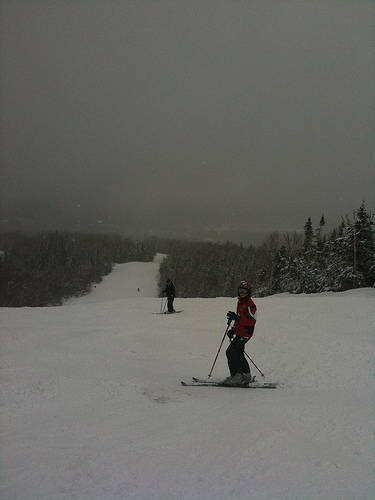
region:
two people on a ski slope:
[154, 278, 282, 388]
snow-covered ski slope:
[2, 253, 373, 498]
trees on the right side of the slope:
[158, 206, 372, 298]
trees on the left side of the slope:
[4, 232, 151, 304]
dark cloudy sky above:
[1, 4, 373, 239]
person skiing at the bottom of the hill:
[135, 286, 141, 291]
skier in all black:
[154, 280, 184, 315]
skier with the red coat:
[183, 278, 282, 387]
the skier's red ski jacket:
[226, 300, 257, 338]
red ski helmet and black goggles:
[238, 281, 249, 293]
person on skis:
[175, 281, 292, 394]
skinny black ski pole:
[201, 303, 235, 380]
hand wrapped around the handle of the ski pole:
[222, 306, 236, 324]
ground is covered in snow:
[0, 249, 371, 499]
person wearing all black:
[158, 280, 179, 310]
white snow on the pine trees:
[245, 209, 374, 294]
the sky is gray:
[0, 0, 373, 258]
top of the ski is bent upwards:
[176, 375, 186, 386]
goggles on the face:
[236, 285, 247, 292]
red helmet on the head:
[234, 276, 256, 302]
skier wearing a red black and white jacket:
[212, 276, 273, 397]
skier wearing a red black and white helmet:
[209, 277, 268, 390]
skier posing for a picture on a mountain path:
[216, 276, 263, 400]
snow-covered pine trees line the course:
[330, 202, 373, 289]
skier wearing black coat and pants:
[153, 279, 181, 318]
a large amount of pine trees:
[15, 227, 123, 306]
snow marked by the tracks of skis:
[53, 406, 302, 498]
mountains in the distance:
[189, 211, 312, 251]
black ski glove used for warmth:
[220, 310, 244, 326]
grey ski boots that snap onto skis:
[218, 366, 253, 392]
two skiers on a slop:
[143, 269, 294, 402]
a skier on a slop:
[153, 273, 190, 323]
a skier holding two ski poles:
[180, 276, 300, 403]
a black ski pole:
[194, 325, 229, 380]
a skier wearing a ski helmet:
[232, 280, 254, 301]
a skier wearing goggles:
[233, 283, 252, 299]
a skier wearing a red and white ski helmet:
[220, 275, 266, 344]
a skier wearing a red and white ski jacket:
[224, 274, 263, 343]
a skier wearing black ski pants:
[221, 275, 257, 382]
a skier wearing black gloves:
[213, 273, 258, 338]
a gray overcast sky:
[28, 18, 356, 205]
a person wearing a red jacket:
[177, 268, 274, 396]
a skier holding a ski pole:
[182, 265, 280, 407]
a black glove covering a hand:
[225, 308, 241, 324]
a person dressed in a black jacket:
[153, 273, 180, 319]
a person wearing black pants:
[146, 271, 184, 317]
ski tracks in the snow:
[231, 429, 303, 493]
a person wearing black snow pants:
[184, 274, 295, 400]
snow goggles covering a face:
[233, 288, 252, 293]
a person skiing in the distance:
[130, 281, 149, 295]